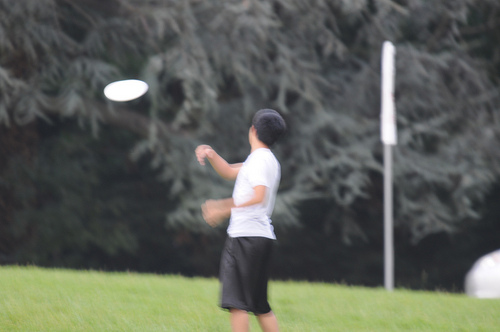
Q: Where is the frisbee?
A: In the mid air.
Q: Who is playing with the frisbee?
A: A boy.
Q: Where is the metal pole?
A: To the right of the boy.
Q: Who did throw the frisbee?
A: The boy.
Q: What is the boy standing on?
A: Grass.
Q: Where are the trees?
A: In a distance behind the boy.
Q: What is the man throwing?
A: Frisbee.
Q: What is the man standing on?
A: Grass.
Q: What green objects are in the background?
A: Trees.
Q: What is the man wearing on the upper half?
A: White shirt.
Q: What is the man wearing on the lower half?
A: Black shorts.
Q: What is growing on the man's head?
A: Hair.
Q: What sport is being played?
A: Frisbee.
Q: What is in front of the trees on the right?
A: Pole.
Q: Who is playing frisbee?
A: A boy.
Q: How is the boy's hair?
A: Short.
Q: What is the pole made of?
A: Metal.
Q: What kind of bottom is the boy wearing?
A: Shorts.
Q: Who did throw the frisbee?
A: The boy.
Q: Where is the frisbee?
A: To the left of the boy.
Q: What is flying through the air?
A: Frisbee.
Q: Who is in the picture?
A: A young man.